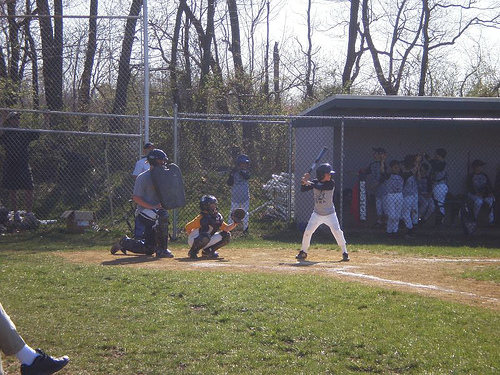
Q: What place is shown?
A: It is a field.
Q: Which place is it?
A: It is a field.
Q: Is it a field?
A: Yes, it is a field.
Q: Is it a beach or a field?
A: It is a field.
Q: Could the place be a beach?
A: No, it is a field.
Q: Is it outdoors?
A: Yes, it is outdoors.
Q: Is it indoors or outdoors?
A: It is outdoors.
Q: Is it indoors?
A: No, it is outdoors.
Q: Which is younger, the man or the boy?
A: The boy is younger than the man.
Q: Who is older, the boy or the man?
A: The man is older than the boy.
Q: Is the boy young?
A: Yes, the boy is young.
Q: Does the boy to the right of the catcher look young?
A: Yes, the boy is young.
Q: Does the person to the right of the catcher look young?
A: Yes, the boy is young.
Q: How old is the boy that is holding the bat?
A: The boy is young.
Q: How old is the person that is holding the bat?
A: The boy is young.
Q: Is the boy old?
A: No, the boy is young.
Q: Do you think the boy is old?
A: No, the boy is young.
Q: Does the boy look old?
A: No, the boy is young.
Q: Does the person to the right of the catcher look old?
A: No, the boy is young.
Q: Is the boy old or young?
A: The boy is young.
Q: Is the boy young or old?
A: The boy is young.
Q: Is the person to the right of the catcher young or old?
A: The boy is young.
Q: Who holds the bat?
A: The boy holds the bat.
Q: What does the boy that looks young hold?
A: The boy holds the bat.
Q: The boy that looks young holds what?
A: The boy holds the bat.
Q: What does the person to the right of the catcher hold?
A: The boy holds the bat.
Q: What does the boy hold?
A: The boy holds the bat.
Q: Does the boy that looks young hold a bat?
A: Yes, the boy holds a bat.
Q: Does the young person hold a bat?
A: Yes, the boy holds a bat.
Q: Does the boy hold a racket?
A: No, the boy holds a bat.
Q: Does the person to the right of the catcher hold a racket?
A: No, the boy holds a bat.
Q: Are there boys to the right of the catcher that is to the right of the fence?
A: Yes, there is a boy to the right of the catcher.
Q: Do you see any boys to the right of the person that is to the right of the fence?
A: Yes, there is a boy to the right of the catcher.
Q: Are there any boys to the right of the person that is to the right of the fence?
A: Yes, there is a boy to the right of the catcher.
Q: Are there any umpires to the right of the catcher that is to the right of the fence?
A: No, there is a boy to the right of the catcher.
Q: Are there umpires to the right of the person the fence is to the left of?
A: No, there is a boy to the right of the catcher.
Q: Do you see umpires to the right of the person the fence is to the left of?
A: No, there is a boy to the right of the catcher.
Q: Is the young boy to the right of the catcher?
A: Yes, the boy is to the right of the catcher.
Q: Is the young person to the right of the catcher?
A: Yes, the boy is to the right of the catcher.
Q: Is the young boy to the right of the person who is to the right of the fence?
A: Yes, the boy is to the right of the catcher.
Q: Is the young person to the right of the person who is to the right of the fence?
A: Yes, the boy is to the right of the catcher.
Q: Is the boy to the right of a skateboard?
A: No, the boy is to the right of the catcher.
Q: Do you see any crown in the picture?
A: No, there are no crowns.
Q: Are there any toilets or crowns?
A: No, there are no crowns or toilets.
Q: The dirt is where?
A: The dirt is on the field.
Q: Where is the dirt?
A: The dirt is on the field.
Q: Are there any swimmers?
A: No, there are no swimmers.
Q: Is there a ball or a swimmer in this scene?
A: No, there are no swimmers or balls.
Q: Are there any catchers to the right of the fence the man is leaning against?
A: Yes, there is a catcher to the right of the fence.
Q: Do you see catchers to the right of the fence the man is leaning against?
A: Yes, there is a catcher to the right of the fence.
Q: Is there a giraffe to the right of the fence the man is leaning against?
A: No, there is a catcher to the right of the fence.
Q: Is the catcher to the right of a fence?
A: Yes, the catcher is to the right of a fence.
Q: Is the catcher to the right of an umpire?
A: No, the catcher is to the right of a fence.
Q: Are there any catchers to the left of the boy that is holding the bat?
A: Yes, there is a catcher to the left of the boy.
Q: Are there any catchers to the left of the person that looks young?
A: Yes, there is a catcher to the left of the boy.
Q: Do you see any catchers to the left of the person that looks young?
A: Yes, there is a catcher to the left of the boy.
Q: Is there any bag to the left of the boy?
A: No, there is a catcher to the left of the boy.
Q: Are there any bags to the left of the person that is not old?
A: No, there is a catcher to the left of the boy.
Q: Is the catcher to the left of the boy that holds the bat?
A: Yes, the catcher is to the left of the boy.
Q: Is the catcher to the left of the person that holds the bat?
A: Yes, the catcher is to the left of the boy.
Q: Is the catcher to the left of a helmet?
A: No, the catcher is to the left of the boy.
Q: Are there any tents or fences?
A: Yes, there is a fence.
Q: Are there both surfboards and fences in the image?
A: No, there is a fence but no surfboards.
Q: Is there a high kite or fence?
A: Yes, there is a high fence.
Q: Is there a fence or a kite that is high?
A: Yes, the fence is high.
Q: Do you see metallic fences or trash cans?
A: Yes, there is a metal fence.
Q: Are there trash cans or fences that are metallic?
A: Yes, the fence is metallic.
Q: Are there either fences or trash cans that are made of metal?
A: Yes, the fence is made of metal.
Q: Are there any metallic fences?
A: Yes, there is a metal fence.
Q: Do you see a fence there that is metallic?
A: Yes, there is a fence that is metallic.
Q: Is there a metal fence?
A: Yes, there is a fence that is made of metal.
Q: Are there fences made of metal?
A: Yes, there is a fence that is made of metal.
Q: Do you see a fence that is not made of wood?
A: Yes, there is a fence that is made of metal.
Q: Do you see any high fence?
A: Yes, there is a high fence.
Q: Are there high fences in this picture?
A: Yes, there is a high fence.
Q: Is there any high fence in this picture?
A: Yes, there is a high fence.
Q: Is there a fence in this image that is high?
A: Yes, there is a fence that is high.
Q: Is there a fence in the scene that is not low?
A: Yes, there is a high fence.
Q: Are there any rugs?
A: No, there are no rugs.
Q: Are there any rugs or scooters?
A: No, there are no rugs or scooters.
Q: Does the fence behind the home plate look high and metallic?
A: Yes, the fence is high and metallic.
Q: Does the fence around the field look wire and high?
A: No, the fence is high but metallic.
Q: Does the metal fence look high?
A: Yes, the fence is high.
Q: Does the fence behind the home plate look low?
A: No, the fence is high.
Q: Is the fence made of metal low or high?
A: The fence is high.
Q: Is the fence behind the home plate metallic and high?
A: Yes, the fence is metallic and high.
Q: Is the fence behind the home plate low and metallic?
A: No, the fence is metallic but high.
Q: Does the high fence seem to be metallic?
A: Yes, the fence is metallic.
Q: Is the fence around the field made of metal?
A: Yes, the fence is made of metal.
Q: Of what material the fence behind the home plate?
A: The fence is made of metal.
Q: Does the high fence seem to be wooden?
A: No, the fence is metallic.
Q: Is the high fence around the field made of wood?
A: No, the fence is made of metal.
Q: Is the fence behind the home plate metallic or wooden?
A: The fence is metallic.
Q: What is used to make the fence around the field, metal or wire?
A: The fence is made of metal.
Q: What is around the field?
A: The fence is around the field.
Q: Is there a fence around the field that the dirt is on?
A: Yes, there is a fence around the field.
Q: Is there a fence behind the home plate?
A: Yes, there is a fence behind the home plate.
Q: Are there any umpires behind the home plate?
A: No, there is a fence behind the home plate.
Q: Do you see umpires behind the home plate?
A: No, there is a fence behind the home plate.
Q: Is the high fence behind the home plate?
A: Yes, the fence is behind the home plate.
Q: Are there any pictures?
A: No, there are no pictures.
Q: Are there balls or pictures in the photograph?
A: No, there are no pictures or balls.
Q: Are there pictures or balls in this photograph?
A: No, there are no pictures or balls.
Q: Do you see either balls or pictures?
A: No, there are no pictures or balls.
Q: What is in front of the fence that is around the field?
A: The home plate is in front of the fence.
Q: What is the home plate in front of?
A: The home plate is in front of the fence.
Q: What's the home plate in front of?
A: The home plate is in front of the fence.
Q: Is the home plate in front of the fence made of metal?
A: Yes, the home plate is in front of the fence.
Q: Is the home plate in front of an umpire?
A: No, the home plate is in front of the fence.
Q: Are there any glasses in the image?
A: No, there are no glasses.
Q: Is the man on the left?
A: Yes, the man is on the left of the image.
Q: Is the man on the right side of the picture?
A: No, the man is on the left of the image.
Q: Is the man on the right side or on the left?
A: The man is on the left of the image.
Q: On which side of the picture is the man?
A: The man is on the left of the image.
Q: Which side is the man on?
A: The man is on the left of the image.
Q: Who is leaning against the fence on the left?
A: The man is leaning against the fence.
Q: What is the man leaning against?
A: The man is leaning against the fence.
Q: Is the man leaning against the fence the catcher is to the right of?
A: Yes, the man is leaning against the fence.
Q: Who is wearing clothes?
A: The man is wearing clothes.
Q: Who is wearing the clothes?
A: The man is wearing clothes.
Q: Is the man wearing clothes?
A: Yes, the man is wearing clothes.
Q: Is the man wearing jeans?
A: No, the man is wearing clothes.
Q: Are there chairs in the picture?
A: No, there are no chairs.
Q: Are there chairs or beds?
A: No, there are no chairs or beds.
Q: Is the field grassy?
A: Yes, the field is grassy.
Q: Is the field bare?
A: No, the field is grassy.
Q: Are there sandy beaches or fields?
A: No, there is a field but it is grassy.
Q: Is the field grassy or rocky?
A: The field is grassy.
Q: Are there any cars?
A: No, there are no cars.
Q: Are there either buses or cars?
A: No, there are no cars or buses.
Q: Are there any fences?
A: Yes, there is a fence.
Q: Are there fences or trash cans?
A: Yes, there is a fence.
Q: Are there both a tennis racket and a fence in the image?
A: No, there is a fence but no rackets.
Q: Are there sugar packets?
A: No, there are no sugar packets.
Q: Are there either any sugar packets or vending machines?
A: No, there are no sugar packets or vending machines.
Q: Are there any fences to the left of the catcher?
A: Yes, there is a fence to the left of the catcher.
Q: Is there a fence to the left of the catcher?
A: Yes, there is a fence to the left of the catcher.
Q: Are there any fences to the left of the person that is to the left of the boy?
A: Yes, there is a fence to the left of the catcher.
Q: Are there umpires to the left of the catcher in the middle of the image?
A: No, there is a fence to the left of the catcher.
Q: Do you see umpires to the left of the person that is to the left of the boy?
A: No, there is a fence to the left of the catcher.